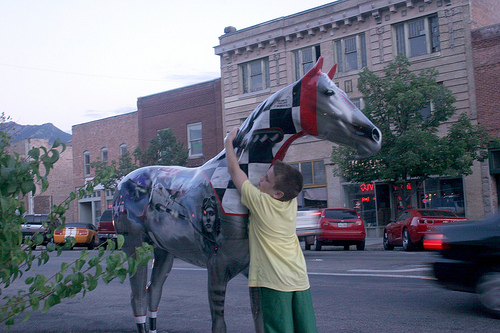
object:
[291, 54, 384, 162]
head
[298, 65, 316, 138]
stripe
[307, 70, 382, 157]
face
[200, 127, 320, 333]
person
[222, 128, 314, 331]
boy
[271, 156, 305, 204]
hair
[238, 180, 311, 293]
shirt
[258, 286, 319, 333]
shorts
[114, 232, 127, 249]
leaf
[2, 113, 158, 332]
tree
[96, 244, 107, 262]
leaf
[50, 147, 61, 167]
leaf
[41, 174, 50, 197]
leaf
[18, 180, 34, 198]
leaf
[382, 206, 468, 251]
car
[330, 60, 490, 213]
tree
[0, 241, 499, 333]
street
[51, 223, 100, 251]
car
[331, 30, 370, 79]
window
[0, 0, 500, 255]
building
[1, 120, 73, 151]
mountain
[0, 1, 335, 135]
sky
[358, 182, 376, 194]
sign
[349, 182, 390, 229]
window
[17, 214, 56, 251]
car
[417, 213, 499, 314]
car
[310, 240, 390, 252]
curb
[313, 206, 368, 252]
car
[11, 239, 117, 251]
curb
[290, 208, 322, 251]
pick-up truck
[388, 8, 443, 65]
window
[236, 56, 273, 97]
window